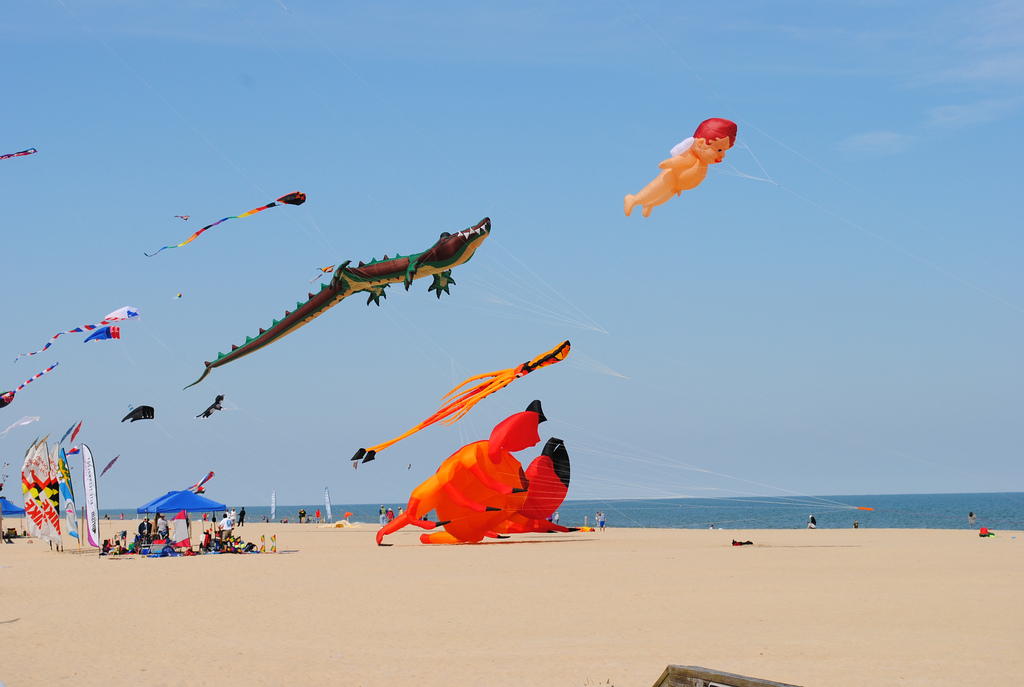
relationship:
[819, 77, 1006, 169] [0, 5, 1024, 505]
clouds in sky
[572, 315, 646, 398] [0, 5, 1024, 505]
clouds in sky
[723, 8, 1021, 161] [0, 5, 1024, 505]
clouds in sky